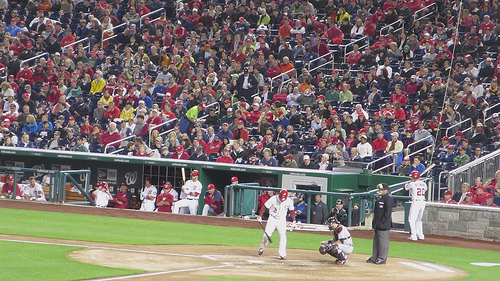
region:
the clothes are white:
[250, 205, 295, 242]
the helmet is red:
[271, 186, 298, 211]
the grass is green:
[35, 212, 136, 244]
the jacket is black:
[368, 198, 407, 228]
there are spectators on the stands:
[195, 28, 468, 120]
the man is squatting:
[312, 201, 352, 260]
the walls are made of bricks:
[442, 209, 497, 236]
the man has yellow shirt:
[75, 70, 110, 96]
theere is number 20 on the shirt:
[407, 181, 439, 205]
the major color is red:
[79, 48, 442, 136]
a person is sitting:
[129, 142, 147, 154]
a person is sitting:
[158, 144, 173, 159]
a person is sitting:
[171, 142, 189, 159]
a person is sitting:
[217, 147, 232, 162]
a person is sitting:
[253, 145, 280, 167]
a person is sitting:
[281, 152, 303, 169]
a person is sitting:
[298, 148, 318, 168]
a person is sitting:
[315, 150, 332, 172]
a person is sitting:
[326, 155, 344, 174]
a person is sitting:
[78, 115, 92, 132]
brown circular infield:
[71, 236, 241, 273]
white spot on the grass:
[468, 249, 495, 279]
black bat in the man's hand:
[253, 217, 283, 243]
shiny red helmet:
[266, 180, 297, 207]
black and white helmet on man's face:
[361, 176, 432, 217]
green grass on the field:
[15, 208, 162, 243]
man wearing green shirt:
[180, 100, 226, 121]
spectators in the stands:
[168, 87, 388, 150]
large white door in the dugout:
[268, 154, 340, 234]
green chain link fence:
[215, 166, 400, 252]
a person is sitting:
[383, 127, 400, 154]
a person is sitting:
[371, 131, 386, 149]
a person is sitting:
[351, 132, 369, 153]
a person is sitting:
[172, 169, 201, 214]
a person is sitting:
[253, 141, 273, 161]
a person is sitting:
[213, 143, 243, 163]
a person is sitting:
[281, 100, 301, 122]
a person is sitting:
[273, 51, 294, 76]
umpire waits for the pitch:
[366, 180, 392, 269]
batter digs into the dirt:
[255, 184, 299, 264]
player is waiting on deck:
[401, 169, 431, 244]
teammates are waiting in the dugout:
[0, 161, 241, 220]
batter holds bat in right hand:
[252, 210, 273, 245]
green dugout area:
[1, 139, 411, 235]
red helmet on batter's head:
[277, 187, 289, 204]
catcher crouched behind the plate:
[317, 212, 355, 266]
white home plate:
[244, 255, 268, 267]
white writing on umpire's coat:
[378, 200, 385, 210]